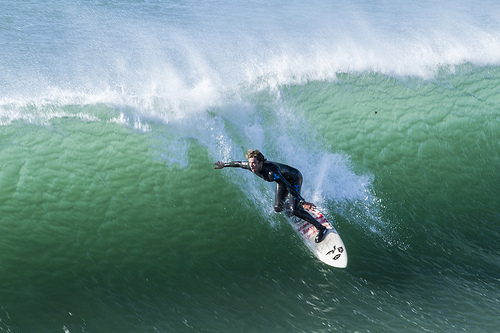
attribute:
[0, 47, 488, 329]
wave — large, cresting, ocean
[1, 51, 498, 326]
water — spray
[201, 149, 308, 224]
surfer — male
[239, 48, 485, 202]
wave — large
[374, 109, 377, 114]
debris — ocean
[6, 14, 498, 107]
sea spray — white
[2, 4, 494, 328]
ocean — blue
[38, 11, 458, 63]
spray — white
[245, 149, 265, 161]
hair — blonde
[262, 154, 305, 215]
wet suit — black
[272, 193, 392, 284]
board — swimming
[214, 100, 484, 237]
ocean — blue, green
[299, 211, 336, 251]
surfing boots — black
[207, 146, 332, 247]
surfer — blue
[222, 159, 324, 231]
wet suit — black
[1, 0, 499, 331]
wave — green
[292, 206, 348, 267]
surfboard — white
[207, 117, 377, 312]
surfboard — red, white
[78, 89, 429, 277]
wave — blue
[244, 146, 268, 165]
hair — blond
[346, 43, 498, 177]
wave — multicolored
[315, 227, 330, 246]
shoes — water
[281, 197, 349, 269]
surfboard — white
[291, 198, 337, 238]
stripes — red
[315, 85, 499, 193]
body — water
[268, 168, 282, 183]
logo — blue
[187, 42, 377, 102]
splash — white, water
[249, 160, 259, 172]
mouth — surfers